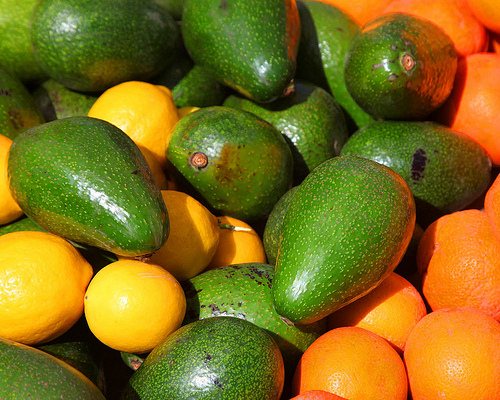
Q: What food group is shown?
A: Fruits.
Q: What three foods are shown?
A: Avocados, oranges and lemons.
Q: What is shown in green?
A: Avocados.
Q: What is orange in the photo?
A: Oranges.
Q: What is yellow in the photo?
A: Lemons.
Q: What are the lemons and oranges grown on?
A: Trees.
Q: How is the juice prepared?
A: Squeezed.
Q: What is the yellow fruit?
A: A lemon.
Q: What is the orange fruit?
A: Oranges.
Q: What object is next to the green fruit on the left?
A: Lemons.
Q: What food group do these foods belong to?
A: Fruits.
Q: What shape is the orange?
A: Spherical.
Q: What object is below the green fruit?
A: Oranges.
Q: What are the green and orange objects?
A: Fruit.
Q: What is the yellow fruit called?
A: A lemon.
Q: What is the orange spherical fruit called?
A: Oranges.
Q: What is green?
A: Avocados.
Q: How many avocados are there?
A: Ten.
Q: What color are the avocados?
A: Green.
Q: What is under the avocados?
A: Oranges.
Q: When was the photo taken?
A: Day time.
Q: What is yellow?
A: The lemons.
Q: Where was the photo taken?
A: Above some fruit.